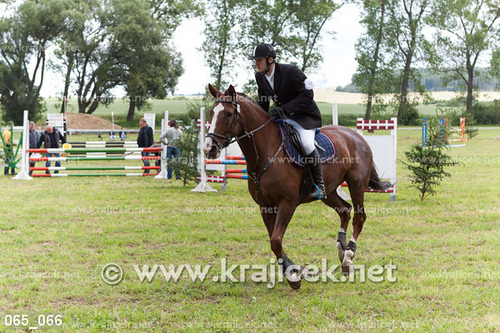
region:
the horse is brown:
[186, 80, 395, 297]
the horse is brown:
[191, 78, 377, 291]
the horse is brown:
[201, 78, 360, 254]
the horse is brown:
[197, 82, 377, 304]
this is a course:
[12, 38, 309, 223]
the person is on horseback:
[144, 11, 462, 276]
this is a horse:
[197, 91, 421, 256]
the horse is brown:
[167, 118, 362, 252]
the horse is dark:
[168, 85, 419, 266]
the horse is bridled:
[174, 105, 271, 160]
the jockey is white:
[235, 63, 383, 180]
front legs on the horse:
[257, 215, 291, 262]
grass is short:
[398, 267, 436, 309]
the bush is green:
[120, 59, 165, 89]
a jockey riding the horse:
[250, 48, 322, 118]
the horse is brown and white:
[201, 105, 394, 279]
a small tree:
[406, 143, 452, 199]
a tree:
[124, 98, 139, 119]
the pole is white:
[20, 113, 35, 178]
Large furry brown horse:
[204, 82, 382, 289]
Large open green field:
[0, 126, 499, 332]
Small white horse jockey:
[249, 44, 326, 202]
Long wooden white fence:
[16, 113, 171, 180]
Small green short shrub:
[397, 121, 454, 206]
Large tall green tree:
[351, 0, 404, 117]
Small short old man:
[42, 126, 63, 176]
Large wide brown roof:
[39, 110, 123, 132]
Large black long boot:
[301, 149, 325, 200]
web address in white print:
[126, 254, 403, 288]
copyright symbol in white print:
[93, 253, 128, 288]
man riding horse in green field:
[191, 33, 388, 293]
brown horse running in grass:
[196, 76, 383, 293]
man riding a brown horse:
[203, 42, 383, 291]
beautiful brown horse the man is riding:
[203, 83, 384, 291]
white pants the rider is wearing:
[282, 116, 317, 153]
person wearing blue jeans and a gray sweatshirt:
[159, 118, 183, 180]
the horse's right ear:
[207, 83, 222, 99]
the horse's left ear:
[225, 83, 236, 100]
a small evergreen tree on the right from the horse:
[401, 116, 460, 202]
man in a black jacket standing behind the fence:
[136, 117, 154, 176]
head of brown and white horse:
[201, 85, 239, 164]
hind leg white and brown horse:
[346, 180, 374, 271]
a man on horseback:
[251, 50, 326, 190]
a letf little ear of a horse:
[203, 83, 223, 100]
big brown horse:
[203, 83, 390, 262]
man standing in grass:
[134, 122, 154, 171]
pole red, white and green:
[25, 148, 159, 155]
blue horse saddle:
[279, 118, 333, 165]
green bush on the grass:
[414, 140, 442, 195]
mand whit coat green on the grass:
[44, 123, 62, 165]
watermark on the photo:
[100, 256, 399, 288]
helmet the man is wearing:
[253, 41, 275, 58]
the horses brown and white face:
[196, 84, 236, 156]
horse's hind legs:
[330, 197, 363, 274]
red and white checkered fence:
[356, 114, 396, 129]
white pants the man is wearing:
[300, 127, 310, 144]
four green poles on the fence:
[63, 148, 122, 179]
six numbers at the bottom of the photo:
[5, 312, 61, 331]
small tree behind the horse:
[407, 108, 454, 193]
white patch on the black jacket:
[303, 76, 315, 92]